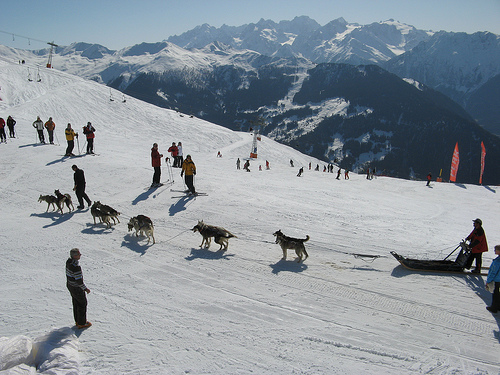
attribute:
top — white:
[28, 117, 46, 130]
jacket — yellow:
[179, 160, 196, 176]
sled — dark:
[391, 243, 475, 276]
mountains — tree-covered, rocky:
[0, 0, 497, 185]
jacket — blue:
[483, 257, 498, 317]